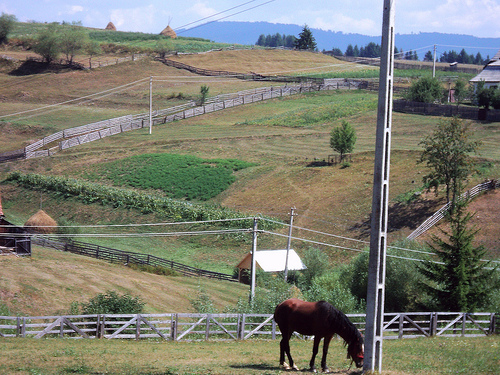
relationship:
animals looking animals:
[272, 298, 367, 373] [272, 298, 367, 373]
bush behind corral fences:
[170, 88, 212, 97] [21, 78, 406, 160]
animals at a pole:
[272, 298, 367, 373] [371, 113, 390, 363]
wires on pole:
[115, 19, 268, 47] [371, 113, 390, 363]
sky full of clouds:
[285, 1, 368, 31] [409, 6, 495, 29]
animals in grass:
[272, 298, 367, 373] [152, 355, 222, 367]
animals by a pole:
[272, 298, 367, 373] [371, 113, 390, 363]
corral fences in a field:
[21, 78, 406, 160] [92, 77, 312, 192]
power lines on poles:
[160, 17, 268, 39] [139, 63, 165, 139]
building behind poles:
[462, 45, 490, 119] [139, 63, 165, 139]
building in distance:
[462, 45, 490, 119] [451, 53, 499, 106]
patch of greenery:
[307, 89, 343, 120] [310, 91, 366, 131]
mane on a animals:
[320, 295, 365, 346] [272, 298, 367, 373]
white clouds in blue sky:
[83, 2, 209, 27] [284, 6, 339, 23]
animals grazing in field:
[272, 298, 367, 373] [92, 77, 312, 192]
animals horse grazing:
[272, 298, 367, 373] [336, 335, 371, 372]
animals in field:
[272, 298, 367, 373] [92, 77, 312, 192]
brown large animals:
[287, 302, 316, 334] [272, 298, 367, 373]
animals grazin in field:
[272, 298, 367, 373] [92, 77, 312, 192]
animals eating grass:
[272, 298, 367, 373] [152, 355, 222, 367]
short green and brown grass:
[191, 274, 246, 301] [244, 183, 301, 211]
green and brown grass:
[185, 132, 354, 220] [152, 355, 222, 367]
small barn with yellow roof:
[462, 45, 490, 119] [460, 42, 490, 93]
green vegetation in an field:
[130, 169, 217, 193] [0, 0, 500, 375]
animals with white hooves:
[272, 298, 367, 373] [266, 352, 310, 375]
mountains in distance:
[162, 12, 421, 77] [451, 53, 499, 106]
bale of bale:
[15, 211, 66, 258] [22, 208, 65, 234]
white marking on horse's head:
[356, 333, 372, 365] [348, 328, 371, 369]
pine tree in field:
[328, 108, 362, 161] [92, 77, 312, 192]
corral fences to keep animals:
[32, 95, 283, 147] [16, 94, 320, 232]